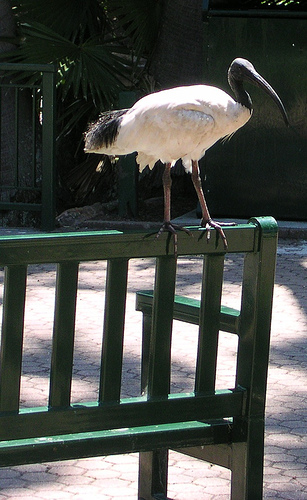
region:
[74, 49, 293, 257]
an ibis on a bench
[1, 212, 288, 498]
the bench is green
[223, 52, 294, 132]
ibis has a black head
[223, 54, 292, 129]
ibis has a black beak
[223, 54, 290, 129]
ibis beak is very long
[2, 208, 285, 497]
bench is made of wrought iron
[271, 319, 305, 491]
walkway is hexagonal cobblestone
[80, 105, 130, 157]
ibis has black feathers at its rear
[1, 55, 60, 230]
green iron railing in the background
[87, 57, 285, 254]
Bird standing on a park bench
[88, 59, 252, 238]
Bird standing on a park bench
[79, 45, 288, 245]
Bird standing on a park bench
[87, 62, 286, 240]
Bird standing on a park bench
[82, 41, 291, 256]
Bird standing on a park bench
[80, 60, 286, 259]
Bird standing on a park bench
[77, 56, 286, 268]
Bird standing on a park bench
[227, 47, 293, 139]
bird with a black beak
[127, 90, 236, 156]
bird with white feathers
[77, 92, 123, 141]
bird with black feathers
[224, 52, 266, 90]
head of a bird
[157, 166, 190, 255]
leg of a bird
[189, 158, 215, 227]
leg of a bird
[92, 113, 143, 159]
tail of a bird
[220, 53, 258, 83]
a head of a bird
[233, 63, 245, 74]
eye of a bird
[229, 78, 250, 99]
neck of a bird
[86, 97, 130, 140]
feather of a bird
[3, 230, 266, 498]
a green bench on the ground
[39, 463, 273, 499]
bricks on the ground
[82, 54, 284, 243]
a bird sitting on the bench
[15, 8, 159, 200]
a tree behind the fence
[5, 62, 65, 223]
a green fence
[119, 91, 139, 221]
a green post on the ground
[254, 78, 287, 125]
the beak of the bird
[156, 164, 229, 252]
the feet of the bird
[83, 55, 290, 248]
a white bird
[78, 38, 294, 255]
bird on edge of green bench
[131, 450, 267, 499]
two bench legs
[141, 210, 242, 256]
two bird claws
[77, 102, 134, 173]
tail of bird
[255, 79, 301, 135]
long bird beak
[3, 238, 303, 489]
octagon shaped pavement bricks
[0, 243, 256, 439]
rails on back of bench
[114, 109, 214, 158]
white bird wing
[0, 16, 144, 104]
green palm tree blades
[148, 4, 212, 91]
brown tree trunk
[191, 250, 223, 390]
green wooden slat on the bench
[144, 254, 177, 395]
green wooden slat on the bench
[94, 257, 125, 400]
green wooden slat on the bench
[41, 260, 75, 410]
green wooden slat on the bench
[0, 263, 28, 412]
green wooden slat on the bench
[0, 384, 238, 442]
green wooden slat on the bench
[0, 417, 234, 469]
green wooden slat on the bench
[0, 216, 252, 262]
green wooden slat on the bench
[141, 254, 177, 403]
green wooden slat on the bench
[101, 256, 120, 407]
A green wooden plank.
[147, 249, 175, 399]
A green wooden plank.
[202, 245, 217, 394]
A green wooden plank.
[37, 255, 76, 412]
A green wooden plank.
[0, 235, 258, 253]
A green wooden plank.